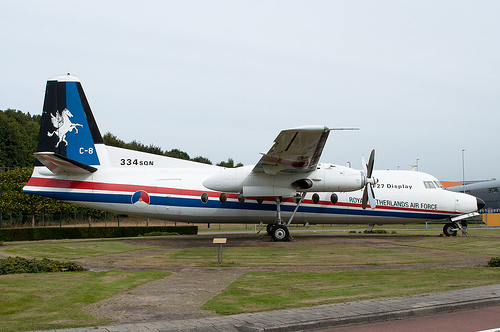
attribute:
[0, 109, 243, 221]
trees — green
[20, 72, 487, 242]
plane — large, white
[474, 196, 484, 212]
nose — black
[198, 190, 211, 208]
window — round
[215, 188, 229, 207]
window — round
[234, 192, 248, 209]
window — round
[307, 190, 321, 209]
window — round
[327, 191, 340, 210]
window — round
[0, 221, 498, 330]
grass — short, green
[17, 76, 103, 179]
tail — black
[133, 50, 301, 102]
sky — smoky, light , blue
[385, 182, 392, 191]
letter — black 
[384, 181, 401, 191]
letter — black 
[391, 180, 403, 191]
letter — black 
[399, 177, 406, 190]
letter — black 